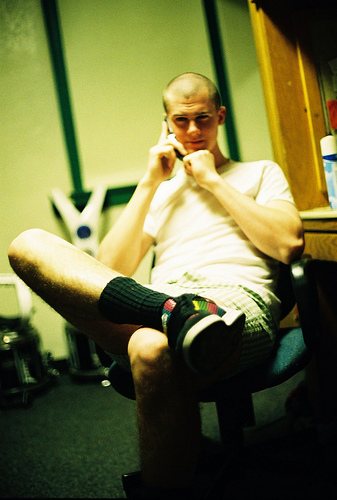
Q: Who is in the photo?
A: A man.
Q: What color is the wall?
A: White.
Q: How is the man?
A: Seated.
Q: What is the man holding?
A: A phone.